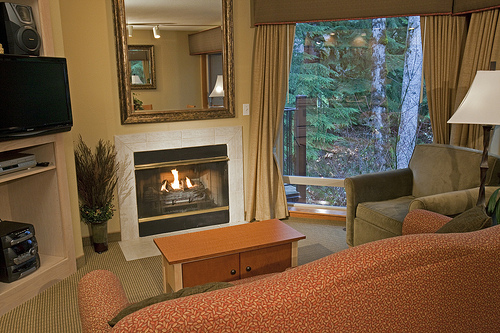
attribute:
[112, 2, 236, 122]
mirror — brown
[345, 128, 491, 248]
armchair — green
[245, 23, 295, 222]
curtains — brown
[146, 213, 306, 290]
table — brown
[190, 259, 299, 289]
cabinet — wooden, small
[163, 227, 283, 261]
table — small, wooden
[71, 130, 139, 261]
plant — potted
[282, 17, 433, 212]
window — open, tall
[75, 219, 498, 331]
couch — white, peach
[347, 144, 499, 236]
green chair — comfortable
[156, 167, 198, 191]
fire — small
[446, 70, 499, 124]
lamp shade — white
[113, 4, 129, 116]
frame — brown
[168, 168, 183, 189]
flame — orange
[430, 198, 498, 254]
pillow — brown